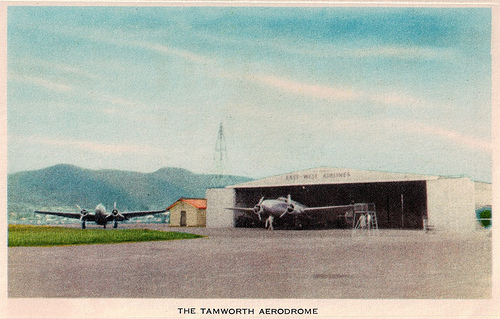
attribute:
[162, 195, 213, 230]
building — tan, yellow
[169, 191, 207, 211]
roof — red, orange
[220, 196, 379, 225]
plane — silver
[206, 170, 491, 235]
hanger — open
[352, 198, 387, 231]
ladder — metal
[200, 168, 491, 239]
hangar — white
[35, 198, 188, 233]
plane — on left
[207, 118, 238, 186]
tower — metal, metallic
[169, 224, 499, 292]
runway — concrete